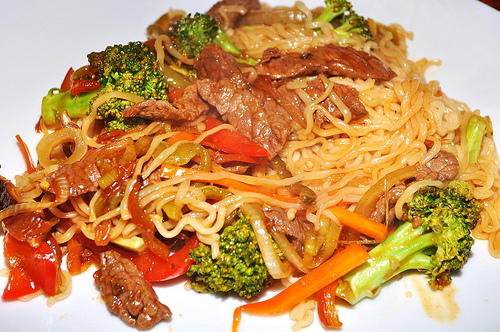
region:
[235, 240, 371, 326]
Julienne carrots on plate.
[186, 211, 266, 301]
Broccoli on the plate.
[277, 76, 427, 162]
Noodles on the plate.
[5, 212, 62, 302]
Red bell pepper on the plate.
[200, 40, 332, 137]
Beef slices in the dish.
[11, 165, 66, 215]
Grilled onions in the dish.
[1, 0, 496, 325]
White plate under the food.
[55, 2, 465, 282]
Brown sauce on the food.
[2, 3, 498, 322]
Asian food on plate.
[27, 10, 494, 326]
Mixed beef, vegetables, and noodles on plate.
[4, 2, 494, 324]
plate of beef and broccoli lo mein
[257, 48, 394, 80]
beef piece sitting on top of beef and broccoli lo mein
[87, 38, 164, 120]
spicey piece of broccoli sitting on top of beef and broccoli lo mein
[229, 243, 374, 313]
sliced carrot in the beef and broccoli lo mein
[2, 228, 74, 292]
red pepper in the beef and broccoli lo mein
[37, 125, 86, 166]
onion sliced in the beef and broccoli lo mein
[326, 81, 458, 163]
noodles in the beef and broccoli lo mein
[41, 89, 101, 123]
broccoli stem mixed in beef and broccoli lo mein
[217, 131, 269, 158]
tip of red bell pepper in the beef and broccoli lo mein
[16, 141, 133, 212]
onion and brown sauce in the beef and broccoli lo mein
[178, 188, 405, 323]
sliced carrots on a plate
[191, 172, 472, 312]
pieces of broccoli on a plate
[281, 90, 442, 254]
cooked noodles on a plate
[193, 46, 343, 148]
pieces of meat on a plate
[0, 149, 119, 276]
sliced onions on a plate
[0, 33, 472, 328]
food on a white plate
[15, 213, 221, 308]
red peppers on a plate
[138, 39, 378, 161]
cooked meat on a plate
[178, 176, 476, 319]
cooked broccoli on a plate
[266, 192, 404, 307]
cooked carrots on a plate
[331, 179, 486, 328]
a piece of broccoli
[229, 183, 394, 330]
a sliced carrot on a plate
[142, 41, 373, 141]
pieces of meat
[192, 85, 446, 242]
cooked noodles on plate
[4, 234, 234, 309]
sliced red peppers on a plate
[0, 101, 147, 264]
cooked onions on a plate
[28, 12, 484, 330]
a white plate with food on it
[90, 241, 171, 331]
A piece of meat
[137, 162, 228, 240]
Some spaghetti strands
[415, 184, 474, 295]
A brocoli head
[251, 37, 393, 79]
Some greasy meat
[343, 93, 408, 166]
Some Long Lo Mein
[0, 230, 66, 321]
Some Big red peppers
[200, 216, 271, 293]
A big brocoli head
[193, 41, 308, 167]
A giant greasy meat piece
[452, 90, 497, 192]
A small portion of green brocoli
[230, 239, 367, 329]
A giant orange carrot